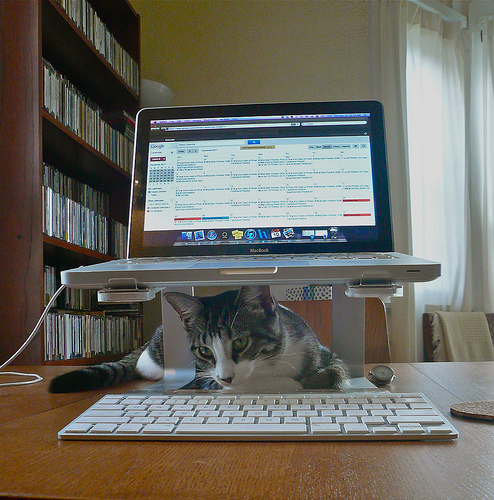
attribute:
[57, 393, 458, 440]
keyboard — white, thin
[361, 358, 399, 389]
face — white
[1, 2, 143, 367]
bookshelf — Wooden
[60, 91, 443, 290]
laptop computer — MacBook 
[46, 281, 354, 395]
cat — brown, white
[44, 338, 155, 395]
tail — striped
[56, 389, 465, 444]
keyboard — white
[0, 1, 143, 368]
wooden shelf — brown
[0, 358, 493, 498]
desk — wooden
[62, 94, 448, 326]
laptop — open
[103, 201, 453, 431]
keyboard — white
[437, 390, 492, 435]
coaster — pressed wood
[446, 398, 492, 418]
coaster — cork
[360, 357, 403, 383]
watch — polished, silver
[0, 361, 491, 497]
table — brown, wooden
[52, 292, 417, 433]
cat — white, black, grey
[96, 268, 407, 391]
stand — metal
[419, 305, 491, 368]
blanket — Cream 